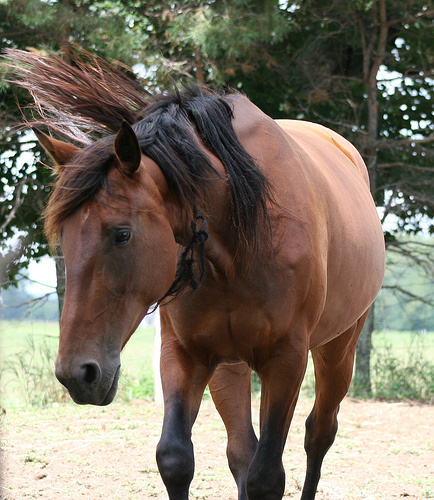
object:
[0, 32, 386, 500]
horse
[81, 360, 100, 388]
nostril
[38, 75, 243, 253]
mane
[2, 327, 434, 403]
grass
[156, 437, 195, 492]
knee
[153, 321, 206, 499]
leg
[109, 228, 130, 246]
eye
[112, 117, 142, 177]
ear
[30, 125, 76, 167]
ear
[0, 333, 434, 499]
ground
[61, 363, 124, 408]
mouth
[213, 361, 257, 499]
leg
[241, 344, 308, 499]
leg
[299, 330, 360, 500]
leg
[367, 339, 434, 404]
bush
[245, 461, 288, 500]
knee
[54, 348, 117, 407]
snout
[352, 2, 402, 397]
tree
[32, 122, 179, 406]
head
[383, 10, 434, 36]
branch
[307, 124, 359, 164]
ropw